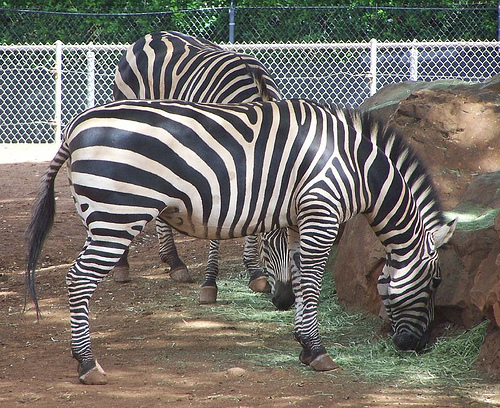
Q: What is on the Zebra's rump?
A: A bushy tail.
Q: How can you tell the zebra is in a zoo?
A: The fence.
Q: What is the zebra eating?
A: Hay.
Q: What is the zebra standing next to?
A: A boulder.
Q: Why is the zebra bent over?
A: To eat.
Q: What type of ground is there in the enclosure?
A: Dirt.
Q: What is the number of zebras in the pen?
A: Two.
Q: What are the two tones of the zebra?
A: Black and white.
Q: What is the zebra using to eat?
A: His mouth.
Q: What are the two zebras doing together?
A: Eating.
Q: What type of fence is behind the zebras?
A: Chain link.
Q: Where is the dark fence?
A: Behind the white fence.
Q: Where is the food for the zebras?
A: Ground.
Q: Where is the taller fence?
A: Behind the white fence.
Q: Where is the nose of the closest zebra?
A: In the food on the ground.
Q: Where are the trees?
A: Beyond the taller fence.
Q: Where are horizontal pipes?
A: Along the top of the shorter fence.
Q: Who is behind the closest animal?
A: A second zebra.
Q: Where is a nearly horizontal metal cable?
A: Along the top of the taller fence?.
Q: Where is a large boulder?
A: Near the faces of the animals.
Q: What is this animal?
A: A zebra.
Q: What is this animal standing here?
A: Zebra.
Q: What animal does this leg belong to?
A: Zebra.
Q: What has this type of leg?
A: A zebra.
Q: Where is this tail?
A: On a zebra.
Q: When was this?
A: Daytime.